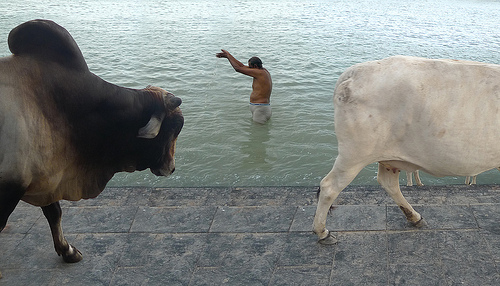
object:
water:
[0, 0, 499, 188]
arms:
[226, 54, 259, 78]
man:
[213, 49, 273, 124]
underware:
[247, 103, 270, 124]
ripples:
[172, 65, 204, 86]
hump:
[6, 19, 90, 74]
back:
[0, 55, 55, 99]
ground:
[0, 185, 497, 284]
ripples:
[208, 131, 275, 184]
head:
[136, 84, 186, 177]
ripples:
[277, 36, 317, 95]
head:
[247, 56, 263, 69]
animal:
[0, 18, 185, 265]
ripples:
[257, 140, 337, 167]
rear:
[332, 55, 500, 113]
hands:
[215, 49, 229, 58]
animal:
[311, 54, 498, 245]